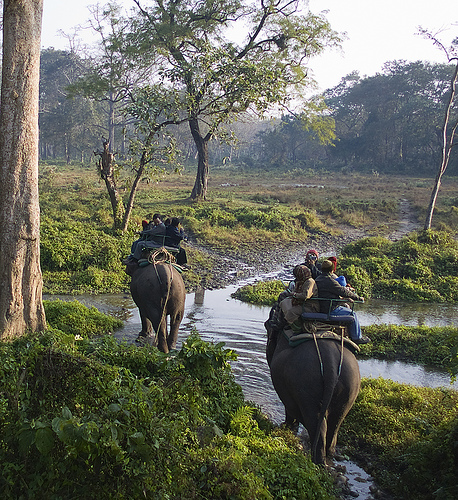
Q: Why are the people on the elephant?
A: Riding it.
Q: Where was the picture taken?
A: Foreign country.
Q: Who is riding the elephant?
A: Men and women.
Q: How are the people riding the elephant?
A: On top of it.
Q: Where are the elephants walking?
A: In water.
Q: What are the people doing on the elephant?
A: Riding it.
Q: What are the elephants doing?
A: Two elephants carrying people.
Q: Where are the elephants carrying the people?
A: On their backs.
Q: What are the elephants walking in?
A: Water.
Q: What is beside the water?
A: Bushes and grass.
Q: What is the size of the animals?
A: Large.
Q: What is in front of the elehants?
A: Trees.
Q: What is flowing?
A: A stream of water.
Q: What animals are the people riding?
A: Elephants.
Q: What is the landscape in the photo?
A: Wetland.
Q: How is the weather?
A: Warm.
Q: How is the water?
A: Calm.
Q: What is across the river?
A: A tree.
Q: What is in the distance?
A: Trees.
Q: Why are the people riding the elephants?
A: Transportation.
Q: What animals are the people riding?
A: Elephants.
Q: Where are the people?
A: On elephants.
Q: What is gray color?
A: Elephants.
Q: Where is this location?
A: Safari.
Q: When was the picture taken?
A: Daytime.